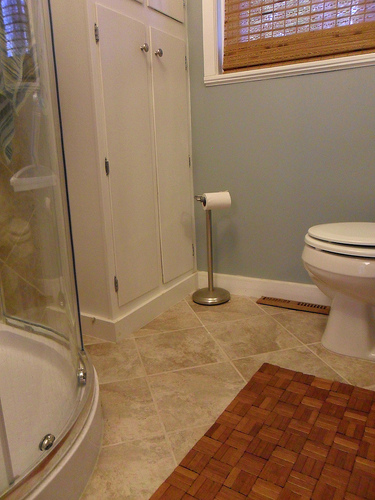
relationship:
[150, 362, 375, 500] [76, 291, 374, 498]
wood on floor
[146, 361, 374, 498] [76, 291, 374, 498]
piece on floor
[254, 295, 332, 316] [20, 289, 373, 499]
floor vent on floor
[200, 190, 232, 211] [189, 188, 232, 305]
tissue on holder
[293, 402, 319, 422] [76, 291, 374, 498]
wood on floor